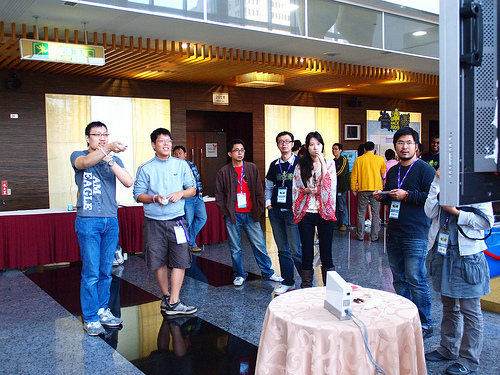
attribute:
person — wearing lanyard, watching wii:
[374, 129, 441, 358]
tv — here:
[440, 0, 500, 208]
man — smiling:
[71, 121, 133, 336]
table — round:
[256, 285, 427, 374]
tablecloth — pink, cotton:
[352, 285, 426, 374]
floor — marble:
[0, 241, 282, 374]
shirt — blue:
[71, 151, 125, 218]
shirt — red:
[234, 167, 253, 212]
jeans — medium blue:
[75, 215, 119, 324]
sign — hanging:
[20, 40, 105, 67]